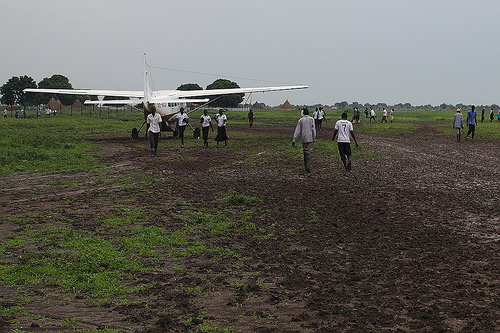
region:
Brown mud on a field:
[192, 150, 324, 280]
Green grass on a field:
[46, 209, 254, 321]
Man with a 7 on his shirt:
[329, 111, 371, 178]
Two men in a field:
[282, 103, 403, 181]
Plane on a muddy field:
[31, 56, 295, 148]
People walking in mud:
[131, 96, 257, 164]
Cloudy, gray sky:
[163, 9, 305, 66]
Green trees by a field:
[7, 62, 82, 115]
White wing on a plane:
[184, 83, 305, 109]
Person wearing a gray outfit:
[453, 101, 468, 143]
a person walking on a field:
[143, 105, 164, 153]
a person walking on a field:
[171, 106, 189, 143]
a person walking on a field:
[198, 108, 213, 145]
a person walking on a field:
[291, 105, 322, 174]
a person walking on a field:
[334, 111, 358, 171]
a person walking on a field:
[451, 107, 464, 138]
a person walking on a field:
[466, 103, 476, 137]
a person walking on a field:
[367, 106, 376, 123]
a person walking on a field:
[380, 108, 389, 124]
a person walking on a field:
[388, 105, 396, 123]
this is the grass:
[16, 121, 39, 140]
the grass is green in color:
[11, 124, 68, 169]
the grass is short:
[11, 125, 51, 168]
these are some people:
[122, 105, 492, 177]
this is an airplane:
[23, 79, 315, 119]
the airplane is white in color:
[152, 88, 173, 101]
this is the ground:
[334, 215, 406, 263]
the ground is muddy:
[338, 197, 428, 274]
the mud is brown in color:
[331, 200, 413, 291]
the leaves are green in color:
[212, 77, 229, 86]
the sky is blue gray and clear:
[5, 1, 496, 119]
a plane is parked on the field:
[16, 50, 307, 132]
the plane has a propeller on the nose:
[20, 52, 307, 142]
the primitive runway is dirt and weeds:
[11, 110, 496, 325]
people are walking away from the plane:
[127, 96, 237, 156]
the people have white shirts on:
[140, 100, 230, 160]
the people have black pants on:
[140, 101, 210, 156]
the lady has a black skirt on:
[210, 105, 230, 145]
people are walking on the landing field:
[241, 100, 496, 175]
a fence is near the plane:
[2, 98, 247, 118]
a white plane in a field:
[18, 51, 331, 151]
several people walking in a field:
[92, 82, 499, 214]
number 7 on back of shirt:
[340, 121, 350, 139]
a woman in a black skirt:
[208, 105, 246, 167]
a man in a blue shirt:
[463, 103, 485, 144]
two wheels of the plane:
[125, 121, 203, 144]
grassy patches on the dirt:
[6, 118, 340, 309]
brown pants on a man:
[296, 138, 325, 185]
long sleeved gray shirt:
[283, 111, 328, 145]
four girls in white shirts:
[133, 106, 234, 143]